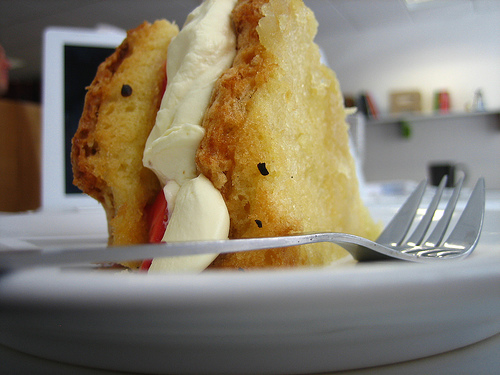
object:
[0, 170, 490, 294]
fork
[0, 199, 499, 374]
plate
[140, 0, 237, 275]
cream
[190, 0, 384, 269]
food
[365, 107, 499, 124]
shelf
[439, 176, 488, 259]
prong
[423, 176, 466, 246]
prong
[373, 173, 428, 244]
prong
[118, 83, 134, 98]
burnt area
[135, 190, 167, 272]
tomato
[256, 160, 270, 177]
burnt area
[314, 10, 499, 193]
wall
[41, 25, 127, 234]
laptop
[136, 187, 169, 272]
strawberry